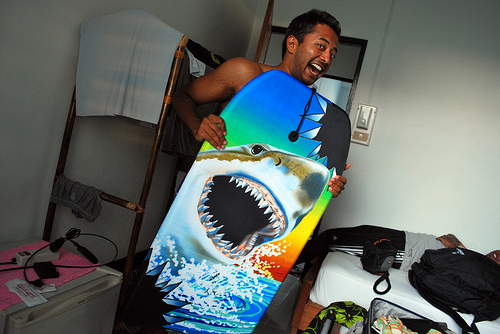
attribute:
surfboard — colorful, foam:
[119, 69, 350, 332]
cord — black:
[1, 227, 120, 290]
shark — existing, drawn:
[158, 142, 331, 267]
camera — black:
[362, 236, 395, 274]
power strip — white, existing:
[14, 249, 63, 265]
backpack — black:
[410, 248, 498, 326]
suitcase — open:
[366, 296, 455, 333]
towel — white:
[74, 11, 184, 124]